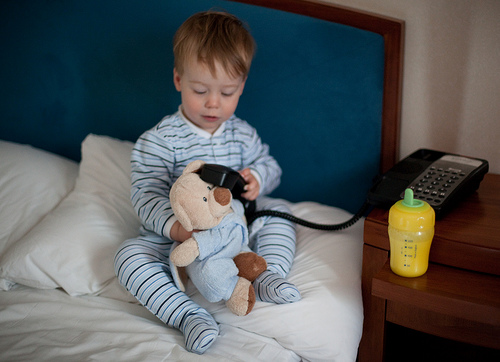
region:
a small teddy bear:
[161, 160, 268, 314]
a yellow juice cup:
[384, 183, 439, 283]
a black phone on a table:
[195, 143, 490, 231]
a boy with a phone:
[111, 9, 302, 352]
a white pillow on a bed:
[4, 127, 368, 360]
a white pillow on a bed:
[0, 139, 84, 289]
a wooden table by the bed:
[358, 148, 497, 360]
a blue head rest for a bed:
[0, 2, 406, 232]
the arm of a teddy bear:
[167, 233, 206, 270]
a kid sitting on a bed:
[136, 25, 293, 331]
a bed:
[6, 2, 342, 359]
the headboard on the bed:
[6, 5, 398, 199]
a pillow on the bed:
[48, 139, 319, 322]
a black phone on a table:
[364, 129, 488, 215]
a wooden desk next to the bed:
[353, 192, 494, 353]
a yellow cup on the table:
[386, 187, 436, 274]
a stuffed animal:
[166, 158, 273, 310]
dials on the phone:
[410, 163, 455, 196]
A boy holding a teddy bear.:
[173, 159, 259, 315]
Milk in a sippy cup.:
[388, 194, 435, 276]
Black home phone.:
[377, 145, 487, 202]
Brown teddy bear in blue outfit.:
[170, 167, 262, 313]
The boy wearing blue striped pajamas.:
[116, 111, 313, 348]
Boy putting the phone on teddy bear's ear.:
[170, 149, 274, 222]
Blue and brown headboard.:
[275, 0, 408, 142]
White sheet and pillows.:
[1, 141, 131, 357]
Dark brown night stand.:
[362, 171, 497, 357]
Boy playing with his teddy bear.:
[121, 7, 301, 355]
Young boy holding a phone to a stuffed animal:
[110, 5, 310, 357]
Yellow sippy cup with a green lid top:
[374, 186, 441, 281]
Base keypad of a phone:
[402, 158, 461, 219]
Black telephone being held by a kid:
[198, 156, 262, 219]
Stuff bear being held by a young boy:
[161, 157, 274, 318]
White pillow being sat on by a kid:
[12, 140, 366, 350]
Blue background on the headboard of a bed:
[4, 7, 158, 114]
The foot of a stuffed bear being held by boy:
[225, 275, 260, 317]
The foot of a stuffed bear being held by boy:
[235, 253, 267, 277]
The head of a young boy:
[167, 6, 261, 129]